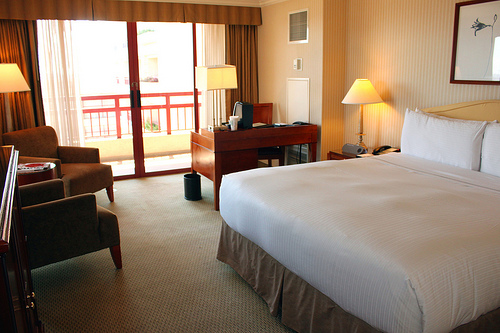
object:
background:
[33, 0, 498, 182]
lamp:
[0, 62, 32, 133]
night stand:
[327, 148, 356, 160]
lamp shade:
[0, 62, 32, 94]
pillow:
[399, 107, 499, 178]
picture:
[448, 0, 500, 86]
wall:
[342, 0, 500, 157]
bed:
[215, 99, 499, 332]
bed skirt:
[216, 219, 500, 332]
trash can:
[183, 173, 202, 201]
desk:
[190, 123, 318, 211]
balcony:
[79, 91, 203, 180]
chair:
[0, 125, 115, 203]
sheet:
[216, 152, 499, 332]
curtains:
[0, 0, 263, 134]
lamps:
[340, 77, 383, 153]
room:
[0, 0, 499, 332]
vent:
[288, 9, 309, 44]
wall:
[254, 1, 323, 167]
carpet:
[31, 170, 298, 332]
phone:
[371, 145, 399, 156]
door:
[58, 21, 201, 183]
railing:
[49, 91, 201, 140]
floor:
[0, 169, 295, 333]